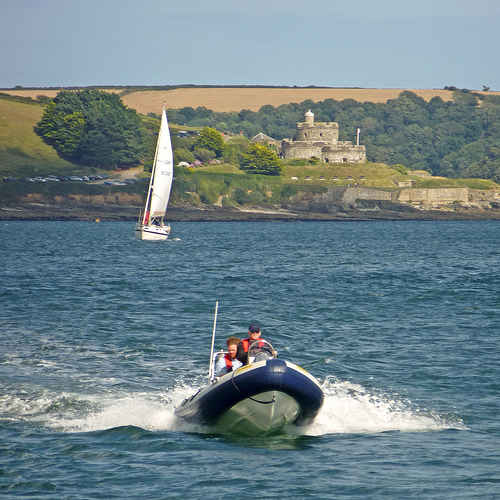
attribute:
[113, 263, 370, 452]
boat — small, white, blue, closest, multicolored, speeding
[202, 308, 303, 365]
people — riding, paired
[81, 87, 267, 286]
sailboat — here, pictured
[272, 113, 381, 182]
building — stone, pictured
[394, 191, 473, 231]
wall — stone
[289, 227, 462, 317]
water — calm, choppy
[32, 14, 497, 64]
sky — cloudless, blue, clear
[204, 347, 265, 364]
vests — orange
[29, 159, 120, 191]
cars — parked, distant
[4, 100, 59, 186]
hills — green, grassy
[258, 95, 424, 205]
castle — stone, old, overlooking, photographed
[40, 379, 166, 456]
waves — behind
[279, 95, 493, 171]
trees — distant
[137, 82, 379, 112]
farmland — yellow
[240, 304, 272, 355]
driver — boating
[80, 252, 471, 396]
waters — breaking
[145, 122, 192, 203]
sail — white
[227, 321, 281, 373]
person — driving